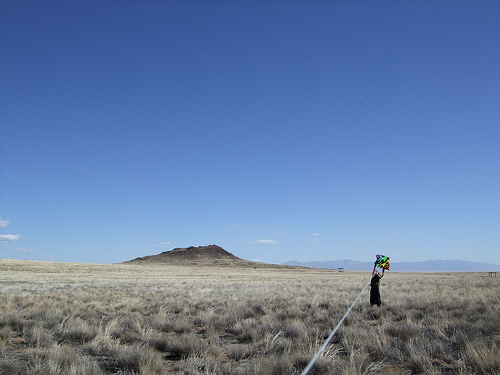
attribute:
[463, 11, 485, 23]
sky — blue, clear, cloudy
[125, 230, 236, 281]
mountain — small, brown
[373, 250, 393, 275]
kite — colorful, red, black, yellow, blue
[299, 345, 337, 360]
string — white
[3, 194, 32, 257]
clouds — white, wispy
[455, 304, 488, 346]
grass — dry, brown, dead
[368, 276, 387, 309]
outfit — black